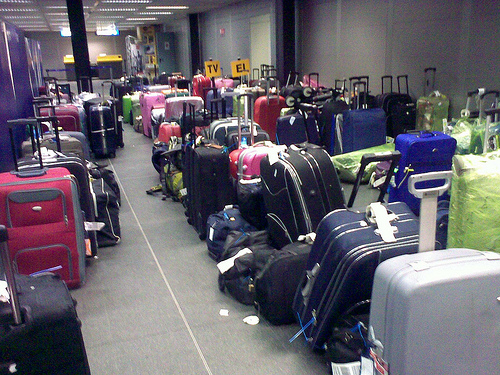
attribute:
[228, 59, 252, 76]
sign — yellow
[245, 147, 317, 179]
handle — black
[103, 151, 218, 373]
line — white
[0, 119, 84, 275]
luggage — piece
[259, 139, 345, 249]
suitcase — black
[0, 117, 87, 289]
suitcase — red, gray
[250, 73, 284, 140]
suitcase — gray, red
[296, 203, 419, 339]
luggage — piece